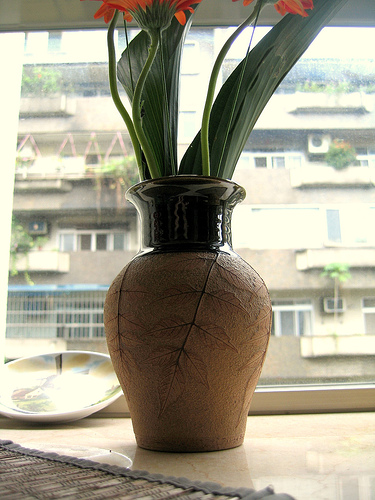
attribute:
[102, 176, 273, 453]
vase — decorative, black, beige, brown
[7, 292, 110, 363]
fence — metal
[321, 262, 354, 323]
tree — small, skinny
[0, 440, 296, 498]
mat — bamboo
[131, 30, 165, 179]
stem — green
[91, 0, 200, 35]
flower — orange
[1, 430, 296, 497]
placement — gray, beige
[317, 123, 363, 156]
flowers — orange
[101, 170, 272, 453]
flower vase — textured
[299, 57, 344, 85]
ground — white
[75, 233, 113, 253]
doors — double glass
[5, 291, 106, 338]
grill — metal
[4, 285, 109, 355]
balcony — covered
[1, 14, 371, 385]
window — open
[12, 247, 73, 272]
balcony — 2nd story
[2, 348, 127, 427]
plate — decorative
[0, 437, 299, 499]
trim — brown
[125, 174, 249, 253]
vase top — black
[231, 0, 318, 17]
flower — orange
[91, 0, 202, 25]
flower — orange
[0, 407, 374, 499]
surface — shiny